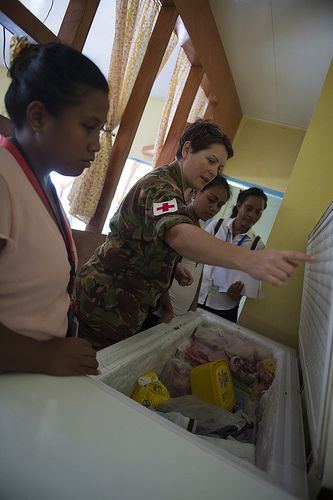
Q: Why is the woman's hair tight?
A: It is pulled back.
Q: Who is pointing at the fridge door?
A: The lady.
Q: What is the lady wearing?
A: An army uniform.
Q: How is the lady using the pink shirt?
A: Wearing it.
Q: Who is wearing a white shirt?
A: A lady.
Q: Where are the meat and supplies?
A: In the freezer.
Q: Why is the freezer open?
A: So they can see in it.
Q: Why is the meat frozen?
A: It is in a freezer.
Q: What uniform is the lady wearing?
A: Camouflage.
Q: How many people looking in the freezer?
A: Four.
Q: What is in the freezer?
A: Food.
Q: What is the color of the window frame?
A: Brown.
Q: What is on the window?
A: Curtrains.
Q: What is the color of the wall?
A: Yellow.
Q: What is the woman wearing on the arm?
A: A red cross.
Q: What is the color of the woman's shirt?
A: Pink.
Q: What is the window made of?
A: Wood.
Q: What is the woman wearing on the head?
A: Sunglasses.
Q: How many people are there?
A: 4.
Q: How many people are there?
A: 4.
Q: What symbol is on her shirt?
A: +.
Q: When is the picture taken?
A: Daytime.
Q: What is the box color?
A: White.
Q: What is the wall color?
A: Yellow.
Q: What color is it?
A: Red.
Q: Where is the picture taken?
A: By the freezer.